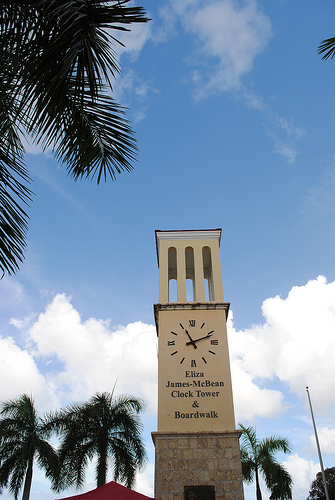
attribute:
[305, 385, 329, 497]
flag pole — tall, metal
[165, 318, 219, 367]
clock — small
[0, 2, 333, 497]
sky — light blue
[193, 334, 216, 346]
hand — minute, clock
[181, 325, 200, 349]
hand — clock, hour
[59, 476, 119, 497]
roof — red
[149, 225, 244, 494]
tower — tall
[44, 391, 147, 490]
tree — PALM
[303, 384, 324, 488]
pole — FLAG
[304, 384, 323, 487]
pole — FLAG, METAL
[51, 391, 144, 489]
tree — PALM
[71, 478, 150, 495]
tent — BURGUNDY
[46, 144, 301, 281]
sky — CLEAR, BLUE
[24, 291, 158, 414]
cloud — white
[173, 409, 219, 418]
word — black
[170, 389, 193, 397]
word — black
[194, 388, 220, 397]
word — black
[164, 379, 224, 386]
word — black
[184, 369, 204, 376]
word — black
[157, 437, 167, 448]
brick — beige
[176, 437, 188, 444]
brick — beige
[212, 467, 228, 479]
brick — beige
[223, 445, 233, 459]
brick — beige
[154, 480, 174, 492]
brick — beige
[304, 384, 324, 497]
pole — skinny, tall